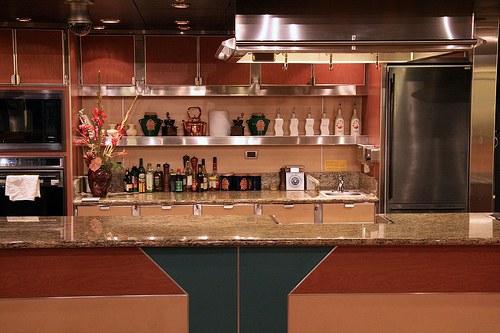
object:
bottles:
[349, 103, 363, 137]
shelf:
[80, 129, 374, 153]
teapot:
[182, 105, 207, 136]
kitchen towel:
[4, 174, 43, 203]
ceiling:
[1, 1, 499, 37]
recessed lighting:
[66, 1, 96, 38]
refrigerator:
[380, 58, 470, 214]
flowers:
[91, 108, 99, 119]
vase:
[87, 165, 112, 198]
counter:
[74, 180, 380, 204]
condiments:
[124, 172, 135, 191]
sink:
[323, 190, 363, 197]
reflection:
[162, 192, 225, 202]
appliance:
[0, 90, 69, 217]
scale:
[284, 165, 307, 191]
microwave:
[0, 89, 64, 151]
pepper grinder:
[162, 161, 171, 193]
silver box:
[356, 142, 373, 166]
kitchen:
[0, 0, 499, 333]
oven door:
[0, 176, 56, 215]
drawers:
[319, 203, 376, 223]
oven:
[1, 154, 67, 216]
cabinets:
[13, 29, 66, 85]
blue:
[212, 246, 219, 264]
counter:
[0, 213, 499, 331]